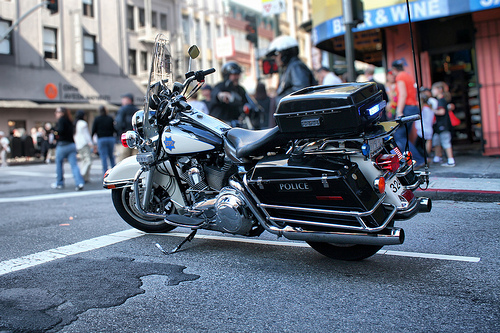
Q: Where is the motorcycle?
A: On the street.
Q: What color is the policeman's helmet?
A: White.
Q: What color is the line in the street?
A: White.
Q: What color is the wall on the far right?
A: Red.